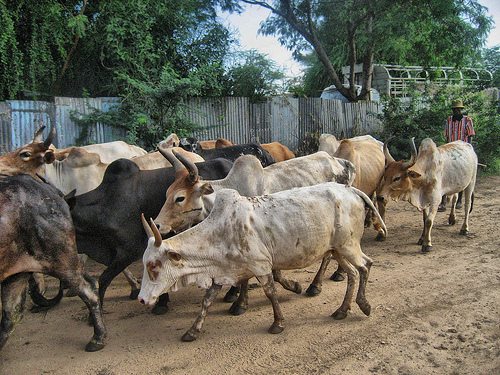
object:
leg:
[252, 268, 284, 326]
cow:
[133, 184, 392, 343]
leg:
[181, 284, 221, 328]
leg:
[333, 255, 361, 312]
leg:
[343, 243, 382, 303]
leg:
[52, 262, 113, 340]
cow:
[1, 169, 112, 353]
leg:
[85, 259, 125, 315]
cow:
[35, 156, 241, 324]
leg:
[421, 200, 440, 248]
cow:
[375, 133, 482, 253]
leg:
[463, 185, 473, 225]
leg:
[446, 191, 458, 217]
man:
[436, 94, 477, 208]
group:
[1, 118, 480, 354]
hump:
[99, 154, 141, 185]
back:
[78, 155, 232, 193]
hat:
[446, 95, 468, 110]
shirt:
[445, 114, 476, 149]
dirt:
[2, 178, 500, 373]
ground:
[1, 171, 499, 375]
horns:
[148, 215, 163, 248]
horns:
[139, 212, 155, 241]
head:
[130, 213, 177, 310]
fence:
[1, 92, 446, 202]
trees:
[229, 1, 433, 105]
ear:
[164, 249, 183, 264]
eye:
[148, 262, 161, 274]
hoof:
[420, 241, 433, 254]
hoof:
[459, 226, 470, 236]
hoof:
[447, 218, 457, 228]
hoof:
[416, 236, 426, 245]